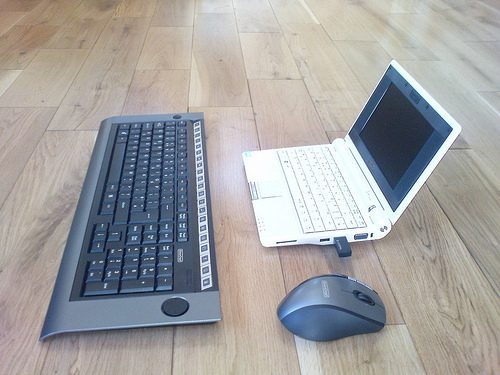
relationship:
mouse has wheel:
[276, 272, 387, 343] [357, 289, 373, 303]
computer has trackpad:
[241, 57, 464, 247] [256, 176, 284, 200]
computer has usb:
[241, 57, 464, 247] [335, 237, 352, 258]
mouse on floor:
[276, 272, 387, 343] [1, 2, 498, 374]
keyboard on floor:
[40, 113, 223, 340] [1, 2, 498, 374]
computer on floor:
[241, 57, 464, 247] [1, 2, 498, 374]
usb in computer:
[335, 237, 352, 258] [241, 57, 464, 247]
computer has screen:
[241, 57, 464, 247] [359, 79, 436, 190]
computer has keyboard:
[241, 57, 464, 247] [277, 148, 368, 234]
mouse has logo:
[276, 272, 387, 343] [320, 277, 331, 298]